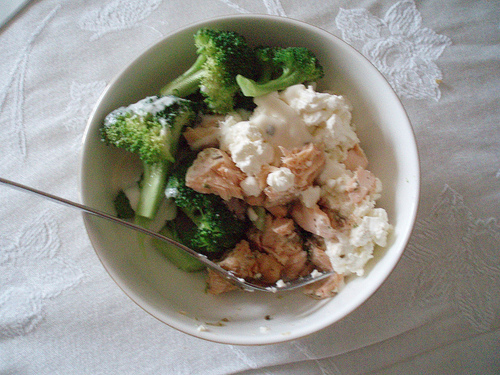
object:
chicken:
[184, 147, 249, 200]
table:
[0, 0, 499, 373]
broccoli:
[100, 95, 200, 217]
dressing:
[101, 96, 191, 124]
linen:
[0, 0, 500, 375]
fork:
[0, 176, 333, 293]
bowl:
[76, 12, 422, 347]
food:
[237, 45, 326, 96]